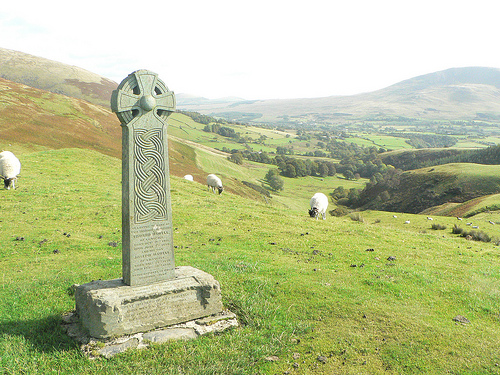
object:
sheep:
[0, 148, 20, 188]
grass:
[0, 146, 500, 375]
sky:
[0, 0, 499, 98]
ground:
[0, 49, 498, 375]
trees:
[277, 161, 297, 179]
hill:
[0, 142, 499, 375]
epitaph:
[70, 71, 218, 338]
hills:
[178, 64, 498, 139]